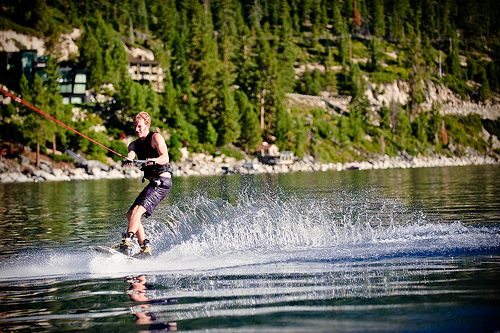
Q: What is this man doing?
A: Waterskiing.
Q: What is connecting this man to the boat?
A: A rope.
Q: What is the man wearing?
A: A life vest.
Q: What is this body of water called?
A: A lake.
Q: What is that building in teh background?
A: A house.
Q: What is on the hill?
A: Trees.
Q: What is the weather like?
A: Sunny.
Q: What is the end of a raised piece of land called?
A: Cliff.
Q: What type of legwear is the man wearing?
A: Shorts.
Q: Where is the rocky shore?
A: By the water.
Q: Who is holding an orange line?
A: A man.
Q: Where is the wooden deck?
A: On the house.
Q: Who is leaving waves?
A: A man.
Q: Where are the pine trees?
A: On the hill.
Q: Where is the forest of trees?
A: On teh hill.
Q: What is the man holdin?
A: A red tether cord.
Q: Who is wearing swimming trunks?
A: A man.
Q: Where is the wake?
A: Behind the man.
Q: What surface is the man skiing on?
A: Lake water.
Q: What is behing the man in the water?
A: A wake.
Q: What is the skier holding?
A: The ski rope.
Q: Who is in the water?
A: A man that is water skiing.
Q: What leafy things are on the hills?
A: Man trees.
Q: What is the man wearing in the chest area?
A: A life vest.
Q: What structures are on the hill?
A: A few houses.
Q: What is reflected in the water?
A: The man's reflection.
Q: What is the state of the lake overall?
A: It is very smooth.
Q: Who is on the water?
A: The man.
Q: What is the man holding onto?
A: A red rope.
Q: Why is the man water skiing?
A: For fun.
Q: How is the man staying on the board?
A: With the rope.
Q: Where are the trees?
A: Surrounding the water.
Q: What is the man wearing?
A: A black suit.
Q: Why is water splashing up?
A: Because of the man's board.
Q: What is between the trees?
A: A building.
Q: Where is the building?
A: On the side of the river.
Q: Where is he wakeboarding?
A: On a lake.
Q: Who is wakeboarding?
A: A man.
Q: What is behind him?
A: The wake.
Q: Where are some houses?
A: Above the shoreline.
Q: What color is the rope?
A: Red.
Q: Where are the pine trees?
A: Along the shoreline.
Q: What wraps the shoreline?
A: Large rocks.